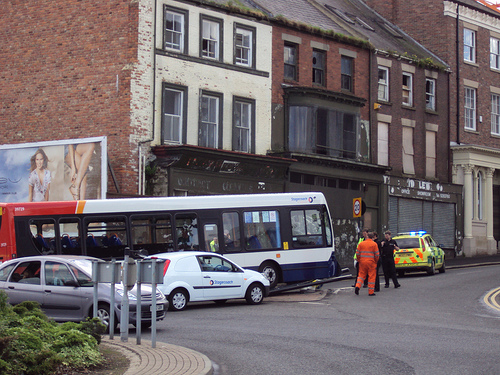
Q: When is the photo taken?
A: Daytime.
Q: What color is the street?
A: Gray.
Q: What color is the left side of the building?
A: Brown.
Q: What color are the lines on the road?
A: Yellow.